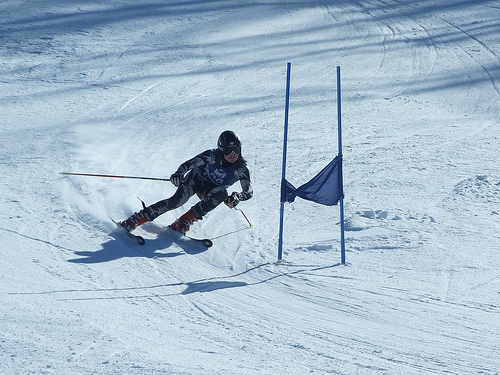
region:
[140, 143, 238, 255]
person skis down hill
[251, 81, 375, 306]
two blue poles near skier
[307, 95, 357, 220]
blue flag on poles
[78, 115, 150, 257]
skier kicks up cloud of snow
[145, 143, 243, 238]
blue and white suit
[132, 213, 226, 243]
skier has red boots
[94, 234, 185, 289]
skier is casting shadow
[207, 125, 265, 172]
skier has black helmet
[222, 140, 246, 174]
skier is wearing goggles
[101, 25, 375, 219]
many tracks in snow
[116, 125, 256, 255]
person is wearing a protective head gear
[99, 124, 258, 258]
person is wearing a snow goggle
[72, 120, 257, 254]
person is on a pair of ski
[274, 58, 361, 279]
a checkpoint area using pole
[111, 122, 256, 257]
person wearing a complete snow suit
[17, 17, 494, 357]
skier is skiing down snowy path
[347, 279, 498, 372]
a flat snowy plain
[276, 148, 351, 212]
a cloth held on by two poles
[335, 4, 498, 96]
track mark on snow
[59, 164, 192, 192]
ski maneuvering stick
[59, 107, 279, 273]
the woman is skiing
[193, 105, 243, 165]
the woman is wearing goggles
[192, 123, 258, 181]
the woman is wearing goggles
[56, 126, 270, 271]
a man riding on some skis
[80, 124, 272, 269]
a man skiing down a slope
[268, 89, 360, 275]
blue trail marker on the slope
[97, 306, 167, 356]
smooth white snow on the slope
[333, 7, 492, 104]
several tracks in the snow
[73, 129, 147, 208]
kicked up snow from the person's skis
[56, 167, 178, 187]
a red and white ski pole in the person's hand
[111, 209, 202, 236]
the skier's red snow boots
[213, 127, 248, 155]
the skier's black helmet and goggles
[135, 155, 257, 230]
the skier's black and white snow suit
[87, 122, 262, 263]
Skier on a mountain trail.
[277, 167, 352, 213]
Blue marker banner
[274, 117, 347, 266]
Two blue poles on the ski trail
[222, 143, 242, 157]
Dark glasses on the skier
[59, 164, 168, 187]
Ski pole in the skier hand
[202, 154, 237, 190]
Writing on the skier's shirt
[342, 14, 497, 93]
Other ski trails in the snow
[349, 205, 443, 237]
Small snow pile next to banner pole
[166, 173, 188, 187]
Skier has black and white glove on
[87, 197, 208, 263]
Skier is pushing snow up with his skis